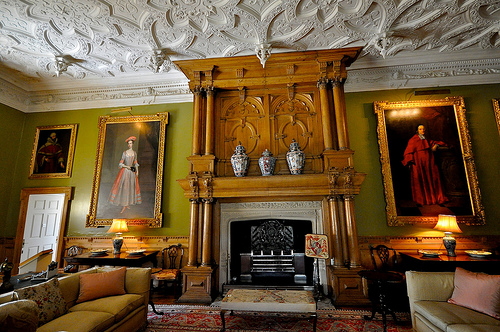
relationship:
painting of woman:
[86, 109, 170, 230] [109, 135, 143, 213]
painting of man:
[374, 97, 488, 228] [401, 124, 453, 207]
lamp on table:
[433, 212, 463, 255] [401, 250, 498, 275]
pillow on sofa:
[448, 266, 500, 318] [407, 270, 500, 331]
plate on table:
[465, 248, 492, 261] [401, 250, 498, 275]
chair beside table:
[368, 245, 405, 283] [401, 250, 498, 275]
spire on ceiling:
[255, 43, 274, 68] [2, 0, 499, 86]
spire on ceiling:
[372, 33, 393, 59] [2, 0, 499, 86]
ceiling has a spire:
[2, 0, 499, 86] [147, 53, 165, 74]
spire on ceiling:
[48, 57, 68, 79] [2, 0, 499, 86]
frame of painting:
[154, 113, 169, 229] [86, 109, 170, 230]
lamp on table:
[106, 219, 129, 254] [64, 250, 162, 271]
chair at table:
[150, 245, 186, 300] [64, 250, 162, 271]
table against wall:
[401, 250, 498, 275] [341, 91, 386, 236]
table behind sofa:
[401, 250, 498, 275] [407, 270, 500, 331]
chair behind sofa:
[368, 245, 405, 283] [407, 270, 500, 331]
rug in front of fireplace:
[136, 303, 415, 331] [219, 202, 318, 291]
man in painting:
[401, 124, 453, 207] [374, 97, 488, 228]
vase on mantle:
[231, 143, 250, 177] [177, 173, 367, 196]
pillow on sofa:
[77, 266, 128, 302] [0, 265, 152, 332]